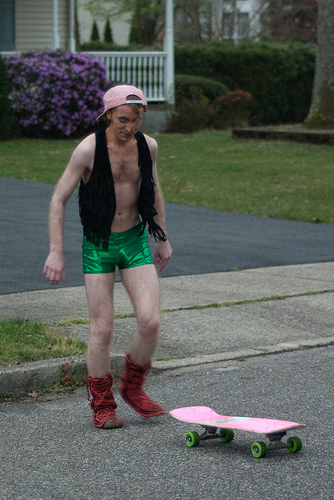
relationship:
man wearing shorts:
[42, 83, 172, 430] [81, 221, 153, 273]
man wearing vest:
[42, 83, 172, 430] [75, 129, 166, 252]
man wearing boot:
[42, 83, 172, 430] [84, 371, 123, 429]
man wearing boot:
[42, 83, 172, 430] [118, 352, 164, 418]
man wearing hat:
[42, 83, 172, 430] [94, 85, 147, 120]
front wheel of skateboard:
[286, 437, 301, 454] [168, 405, 306, 457]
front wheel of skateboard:
[250, 440, 268, 460] [168, 405, 306, 457]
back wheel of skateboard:
[182, 429, 200, 449] [168, 405, 306, 457]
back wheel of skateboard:
[218, 429, 233, 442] [168, 405, 306, 457]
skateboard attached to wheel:
[168, 405, 306, 457] [183, 431, 199, 446]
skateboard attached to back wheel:
[168, 405, 306, 457] [218, 428, 233, 443]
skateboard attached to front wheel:
[168, 405, 306, 457] [286, 437, 301, 454]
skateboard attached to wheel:
[168, 405, 306, 457] [250, 439, 267, 459]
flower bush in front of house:
[3, 46, 109, 135] [0, 0, 176, 133]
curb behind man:
[0, 352, 127, 397] [42, 83, 172, 430]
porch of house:
[1, 51, 164, 103] [0, 0, 176, 133]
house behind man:
[0, 0, 176, 133] [42, 83, 172, 430]